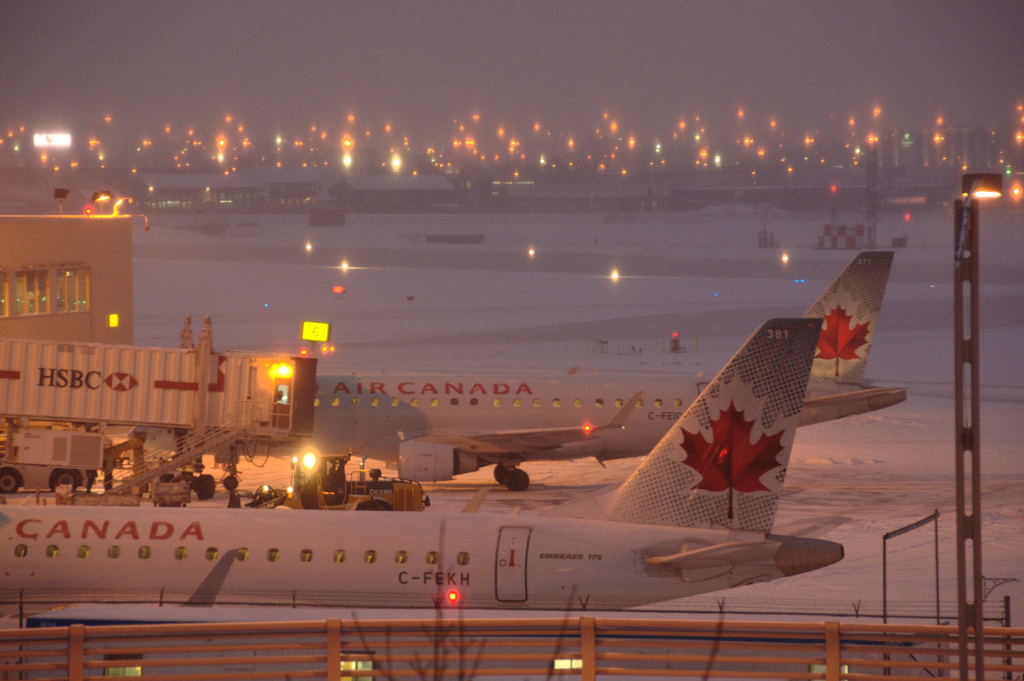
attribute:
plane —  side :
[0, 308, 854, 660]